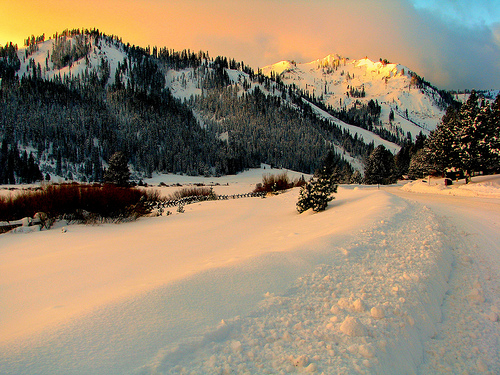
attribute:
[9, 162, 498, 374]
ground — snowy, covered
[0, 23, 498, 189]
mountains — distant, reflecting, covered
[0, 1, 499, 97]
sky — blue, orange, revealed, bright, cloudy, gray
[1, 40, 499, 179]
trees — green, tall, covered, pine, brown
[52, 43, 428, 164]
snow — white, rough, bright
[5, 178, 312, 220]
bushes — red